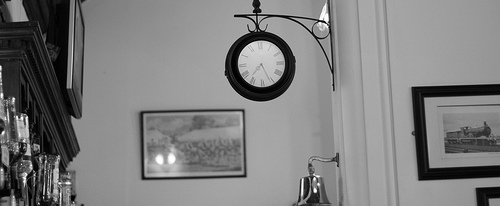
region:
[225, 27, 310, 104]
A hanging clock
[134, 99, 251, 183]
A picture on the wall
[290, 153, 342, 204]
A silver bell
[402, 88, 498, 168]
A picture of a train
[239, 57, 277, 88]
The clock says 7:26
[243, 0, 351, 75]
Clock hanging rod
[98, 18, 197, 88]
A blank white wall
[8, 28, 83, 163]
A wooden desk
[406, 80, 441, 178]
Black picture frame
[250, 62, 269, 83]
The minute and hour hands of the clock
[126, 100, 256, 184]
THE PICTURE IS BLACK AND WHITE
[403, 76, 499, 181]
THE PICTURE HAS A BLACK FRAME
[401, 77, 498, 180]
THE PICTURE HAS A WHITE MAT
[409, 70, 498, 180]
THE PICTURE IS ON THE WALL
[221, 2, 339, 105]
THE CLOCK IS HANGING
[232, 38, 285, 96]
THE CLOCK HAS ROMAN NUMERALS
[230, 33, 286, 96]
THE CLOCK HAS A WHITE FACE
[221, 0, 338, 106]
THE CLOCK READS 7:25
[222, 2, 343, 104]
THE BELL IS BENEATH THE CLOCK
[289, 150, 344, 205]
THE BELL IS METAL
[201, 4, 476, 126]
a clock hanging on wall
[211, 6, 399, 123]
a black clock hanging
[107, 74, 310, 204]
a picture on the wall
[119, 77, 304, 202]
a framed picture on the wall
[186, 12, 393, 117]
a black and white clock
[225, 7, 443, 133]
clock hanging from pole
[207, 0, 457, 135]
clock hanging from metal pole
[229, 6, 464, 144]
metal pole on the wall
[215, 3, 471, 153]
metal clock on the wall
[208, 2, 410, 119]
clock that is inside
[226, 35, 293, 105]
a clock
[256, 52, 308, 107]
a clock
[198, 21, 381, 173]
a clock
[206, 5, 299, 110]
a clock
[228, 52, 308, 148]
a clock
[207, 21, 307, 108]
The clock is hanging.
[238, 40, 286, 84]
The clock face is white.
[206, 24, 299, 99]
The clock frame is black.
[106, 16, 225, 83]
The wall is white.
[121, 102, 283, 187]
Photo on the wall.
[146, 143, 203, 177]
Light reflecting in the photo.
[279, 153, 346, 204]
Bell on the wall.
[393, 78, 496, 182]
The picture frame is black.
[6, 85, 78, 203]
Upside down wine bottles.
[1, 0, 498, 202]
Photo is in black and white.